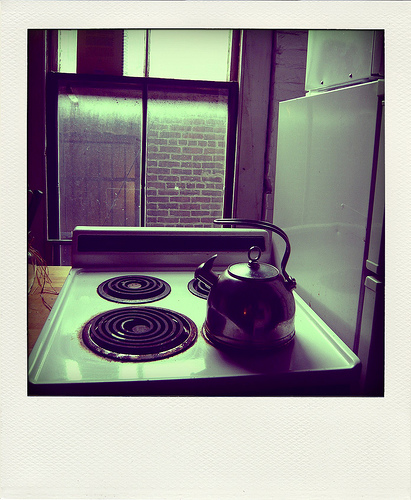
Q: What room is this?
A: Kitchen.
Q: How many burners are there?
A: Four.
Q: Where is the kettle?
A: On a burner.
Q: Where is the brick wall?
A: Outside the window.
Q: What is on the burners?
A: Rust.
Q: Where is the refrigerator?
A: Next to the stove.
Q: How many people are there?
A: None.